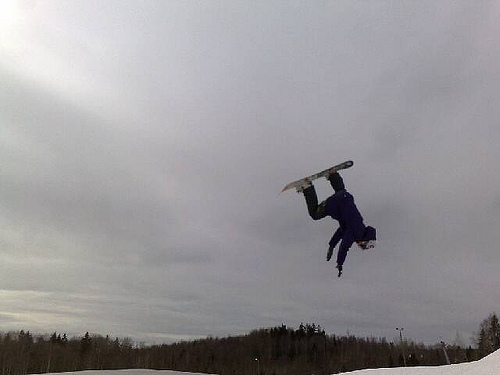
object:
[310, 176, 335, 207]
square opening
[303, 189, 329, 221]
leg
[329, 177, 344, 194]
leg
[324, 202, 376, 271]
jacket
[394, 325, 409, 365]
pole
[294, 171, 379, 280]
person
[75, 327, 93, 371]
trees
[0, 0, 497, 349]
overcast sky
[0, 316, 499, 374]
hill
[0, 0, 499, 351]
clouds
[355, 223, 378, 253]
head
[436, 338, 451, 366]
pole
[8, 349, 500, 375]
snow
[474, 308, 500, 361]
green trees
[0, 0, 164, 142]
light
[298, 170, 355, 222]
pants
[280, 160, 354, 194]
snowboard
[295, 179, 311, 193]
feet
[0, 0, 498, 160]
air